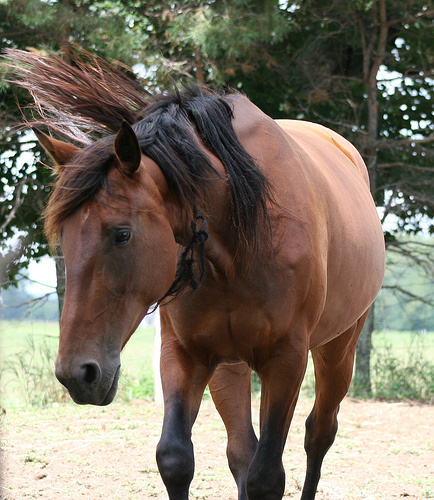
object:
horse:
[0, 32, 386, 500]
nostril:
[81, 360, 100, 388]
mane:
[38, 75, 243, 253]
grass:
[2, 327, 434, 403]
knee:
[156, 437, 195, 492]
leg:
[153, 321, 206, 499]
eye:
[109, 228, 130, 246]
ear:
[112, 117, 142, 177]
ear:
[30, 125, 76, 167]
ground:
[0, 333, 434, 499]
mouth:
[61, 363, 124, 408]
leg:
[213, 361, 257, 499]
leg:
[241, 344, 308, 499]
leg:
[299, 330, 360, 500]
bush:
[367, 339, 434, 404]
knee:
[245, 461, 288, 500]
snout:
[54, 348, 117, 407]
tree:
[352, 2, 402, 397]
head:
[32, 122, 179, 406]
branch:
[383, 10, 434, 36]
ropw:
[307, 124, 359, 164]